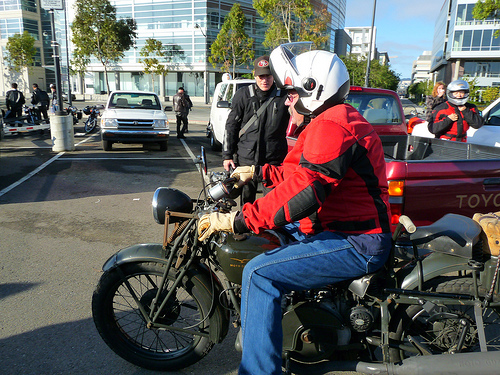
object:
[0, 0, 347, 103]
building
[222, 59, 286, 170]
man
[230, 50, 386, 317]
man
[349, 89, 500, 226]
pickup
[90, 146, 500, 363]
motorcycle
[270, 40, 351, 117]
helmet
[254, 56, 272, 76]
baseball cap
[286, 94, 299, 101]
sunglasses